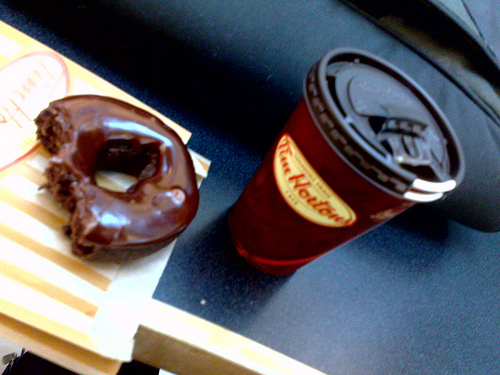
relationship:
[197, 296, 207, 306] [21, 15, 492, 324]
spot on table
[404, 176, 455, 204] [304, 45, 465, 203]
part of lid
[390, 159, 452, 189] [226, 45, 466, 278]
lid of bottle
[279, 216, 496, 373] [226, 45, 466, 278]
table with bottle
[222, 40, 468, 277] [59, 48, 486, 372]
coffee on stand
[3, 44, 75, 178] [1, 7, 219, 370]
graphic on bag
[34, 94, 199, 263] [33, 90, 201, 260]
cake on pastry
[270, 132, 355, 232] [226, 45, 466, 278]
label on bottle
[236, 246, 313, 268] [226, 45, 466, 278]
swirl on bottle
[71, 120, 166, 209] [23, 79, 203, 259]
hole in donut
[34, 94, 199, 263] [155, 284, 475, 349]
cake on table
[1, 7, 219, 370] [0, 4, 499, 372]
bag on table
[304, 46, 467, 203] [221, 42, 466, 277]
lid on container